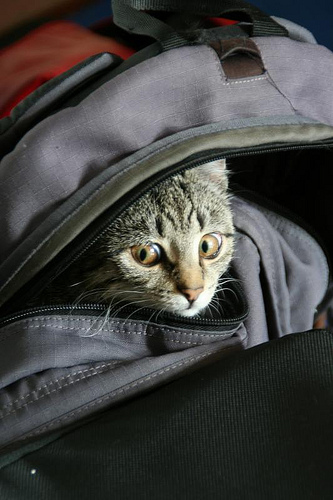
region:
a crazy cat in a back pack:
[7, 106, 271, 331]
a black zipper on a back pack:
[44, 304, 108, 317]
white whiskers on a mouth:
[98, 294, 131, 322]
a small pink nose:
[180, 283, 206, 304]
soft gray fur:
[159, 197, 208, 223]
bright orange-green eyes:
[125, 232, 236, 266]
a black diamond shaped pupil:
[140, 249, 145, 259]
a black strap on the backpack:
[118, 4, 281, 44]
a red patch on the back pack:
[20, 24, 94, 60]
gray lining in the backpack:
[174, 144, 198, 152]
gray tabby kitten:
[40, 157, 235, 320]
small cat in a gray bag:
[3, 19, 326, 447]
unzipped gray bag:
[4, 4, 328, 461]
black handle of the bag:
[112, 0, 288, 36]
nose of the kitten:
[182, 287, 197, 300]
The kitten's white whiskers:
[68, 278, 244, 337]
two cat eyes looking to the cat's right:
[131, 236, 219, 265]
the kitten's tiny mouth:
[171, 307, 202, 313]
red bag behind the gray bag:
[0, 16, 135, 121]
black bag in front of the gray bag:
[1, 330, 326, 499]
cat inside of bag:
[80, 207, 246, 339]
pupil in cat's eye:
[199, 238, 214, 257]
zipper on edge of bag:
[64, 298, 132, 319]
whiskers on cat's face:
[74, 283, 154, 334]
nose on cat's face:
[177, 283, 211, 304]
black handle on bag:
[114, 2, 285, 56]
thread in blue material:
[81, 346, 161, 386]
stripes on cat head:
[148, 209, 208, 238]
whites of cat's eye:
[211, 227, 226, 246]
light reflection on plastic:
[76, 50, 112, 80]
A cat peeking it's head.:
[91, 148, 255, 336]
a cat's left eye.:
[194, 222, 236, 280]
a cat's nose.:
[176, 270, 213, 307]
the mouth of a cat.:
[179, 289, 218, 327]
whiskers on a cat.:
[205, 261, 256, 308]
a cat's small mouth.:
[175, 300, 207, 331]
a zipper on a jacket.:
[8, 304, 260, 363]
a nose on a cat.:
[173, 232, 206, 303]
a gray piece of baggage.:
[0, 314, 246, 465]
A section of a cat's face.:
[160, 226, 230, 308]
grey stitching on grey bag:
[61, 315, 145, 338]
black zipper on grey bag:
[32, 303, 101, 314]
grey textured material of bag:
[125, 78, 198, 126]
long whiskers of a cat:
[75, 282, 174, 330]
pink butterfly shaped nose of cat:
[180, 284, 204, 302]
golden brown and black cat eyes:
[115, 230, 234, 267]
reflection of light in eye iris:
[201, 239, 214, 254]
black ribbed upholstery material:
[237, 351, 316, 441]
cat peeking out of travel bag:
[84, 148, 257, 320]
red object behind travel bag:
[8, 9, 143, 124]